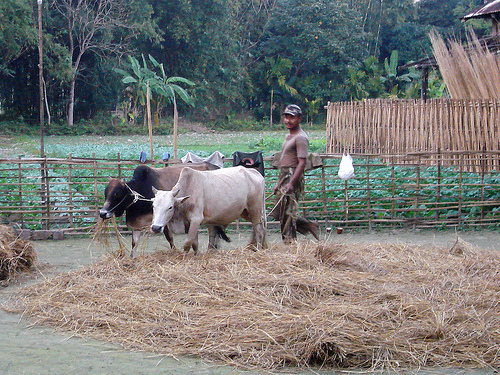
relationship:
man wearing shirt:
[274, 102, 322, 243] [275, 133, 308, 166]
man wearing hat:
[274, 102, 322, 243] [283, 103, 303, 116]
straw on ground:
[295, 315, 337, 337] [0, 232, 499, 374]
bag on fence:
[337, 151, 355, 181] [0, 149, 498, 225]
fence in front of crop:
[0, 149, 498, 225] [46, 184, 88, 215]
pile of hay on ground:
[14, 239, 499, 372] [0, 232, 499, 374]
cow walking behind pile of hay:
[149, 166, 268, 253] [14, 239, 499, 372]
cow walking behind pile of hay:
[98, 165, 208, 257] [14, 239, 499, 372]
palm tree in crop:
[147, 52, 197, 158] [128, 152, 149, 160]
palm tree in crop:
[116, 53, 160, 158] [157, 145, 171, 155]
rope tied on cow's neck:
[122, 181, 143, 213] [103, 176, 137, 218]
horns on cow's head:
[149, 184, 180, 198] [147, 184, 191, 209]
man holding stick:
[274, 102, 322, 243] [265, 185, 279, 202]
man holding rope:
[274, 102, 322, 243] [122, 181, 143, 213]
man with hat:
[274, 102, 322, 243] [283, 103, 303, 116]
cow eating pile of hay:
[149, 166, 268, 253] [14, 239, 499, 372]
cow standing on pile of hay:
[149, 166, 268, 253] [14, 239, 499, 372]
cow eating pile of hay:
[98, 165, 208, 257] [14, 239, 499, 372]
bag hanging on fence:
[337, 151, 355, 181] [0, 149, 498, 225]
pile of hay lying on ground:
[14, 239, 499, 372] [0, 232, 499, 374]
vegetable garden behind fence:
[3, 144, 498, 227] [0, 149, 498, 225]